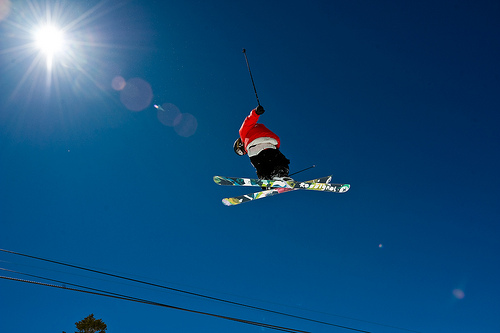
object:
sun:
[26, 18, 70, 59]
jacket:
[238, 109, 281, 154]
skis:
[220, 174, 335, 207]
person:
[232, 105, 294, 193]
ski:
[210, 174, 350, 194]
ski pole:
[240, 48, 262, 106]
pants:
[248, 148, 291, 192]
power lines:
[0, 274, 308, 332]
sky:
[0, 0, 498, 332]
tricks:
[213, 47, 350, 207]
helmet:
[232, 138, 247, 157]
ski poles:
[288, 164, 316, 178]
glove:
[254, 104, 265, 117]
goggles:
[235, 146, 244, 157]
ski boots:
[263, 171, 295, 188]